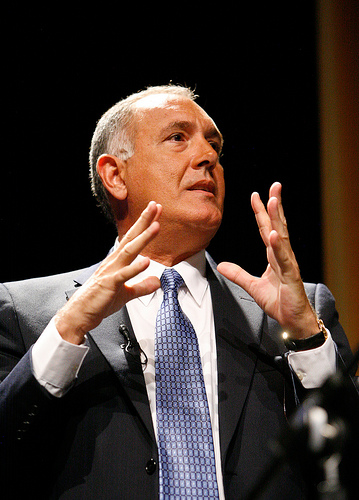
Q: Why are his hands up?
A: Making a point.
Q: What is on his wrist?
A: Watch.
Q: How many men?
A: One.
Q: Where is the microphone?
A: On the left lapel.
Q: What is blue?
A: Tie.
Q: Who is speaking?
A: Man.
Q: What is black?
A: Coat.